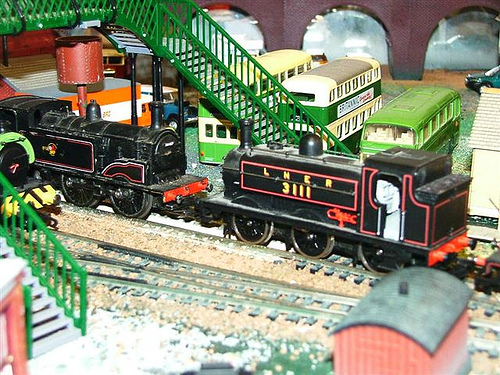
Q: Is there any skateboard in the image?
A: No, there are no skateboards.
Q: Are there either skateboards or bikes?
A: No, there are no skateboards or bikes.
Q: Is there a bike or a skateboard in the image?
A: No, there are no skateboards or bikes.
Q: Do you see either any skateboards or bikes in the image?
A: No, there are no skateboards or bikes.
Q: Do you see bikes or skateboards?
A: No, there are no skateboards or bikes.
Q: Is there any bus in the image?
A: Yes, there is a bus.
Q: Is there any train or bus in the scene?
A: Yes, there is a bus.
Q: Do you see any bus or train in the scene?
A: Yes, there is a bus.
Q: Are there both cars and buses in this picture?
A: Yes, there are both a bus and a car.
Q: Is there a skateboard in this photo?
A: No, there are no skateboards.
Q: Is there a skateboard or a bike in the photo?
A: No, there are no skateboards or bikes.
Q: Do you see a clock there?
A: No, there are no clocks.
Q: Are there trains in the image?
A: Yes, there is a train.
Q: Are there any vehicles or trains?
A: Yes, there is a train.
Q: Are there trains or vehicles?
A: Yes, there is a train.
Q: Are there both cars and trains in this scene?
A: Yes, there are both a train and a car.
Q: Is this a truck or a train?
A: This is a train.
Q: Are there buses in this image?
A: Yes, there is a bus.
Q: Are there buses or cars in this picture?
A: Yes, there is a bus.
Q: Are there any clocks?
A: No, there are no clocks.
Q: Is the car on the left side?
A: No, the car is on the right of the image.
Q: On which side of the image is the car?
A: The car is on the right of the image.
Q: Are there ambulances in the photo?
A: No, there are no ambulances.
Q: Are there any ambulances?
A: No, there are no ambulances.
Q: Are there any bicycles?
A: No, there are no bicycles.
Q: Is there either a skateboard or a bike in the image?
A: No, there are no bikes or skateboards.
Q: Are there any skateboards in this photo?
A: No, there are no skateboards.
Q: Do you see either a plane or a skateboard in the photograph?
A: No, there are no skateboards or airplanes.